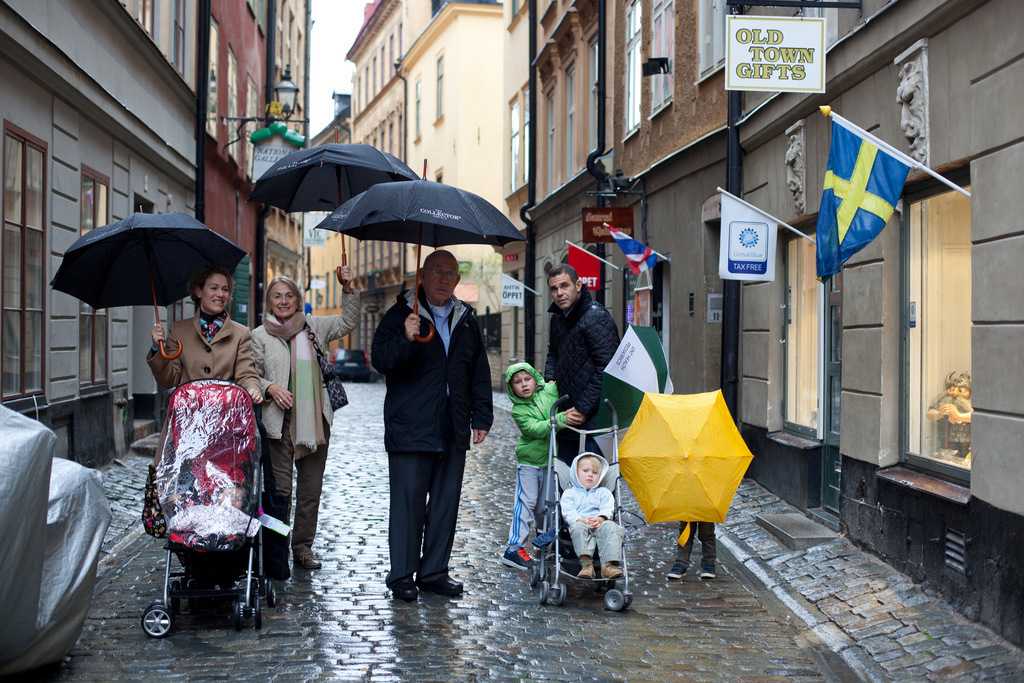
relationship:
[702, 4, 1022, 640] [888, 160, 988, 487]
building has window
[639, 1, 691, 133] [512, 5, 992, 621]
window on building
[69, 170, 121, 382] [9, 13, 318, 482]
window on building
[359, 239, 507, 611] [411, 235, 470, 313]
man has head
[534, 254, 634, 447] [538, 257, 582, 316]
man has head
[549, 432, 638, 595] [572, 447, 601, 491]
boy has head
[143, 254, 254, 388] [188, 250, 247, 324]
woman has head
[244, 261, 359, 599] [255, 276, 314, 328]
woman has head